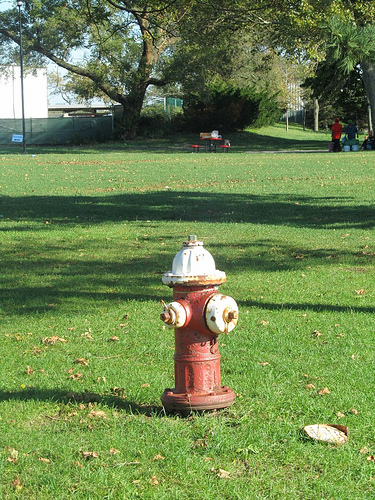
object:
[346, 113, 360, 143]
person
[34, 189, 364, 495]
leaves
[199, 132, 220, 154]
picnic table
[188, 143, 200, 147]
seat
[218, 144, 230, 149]
seat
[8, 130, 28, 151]
sign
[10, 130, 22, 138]
letters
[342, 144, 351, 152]
bucket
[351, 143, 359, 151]
bucket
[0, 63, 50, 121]
building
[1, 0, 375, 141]
tree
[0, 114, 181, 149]
fence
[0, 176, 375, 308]
shadows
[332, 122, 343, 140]
shirt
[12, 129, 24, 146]
sign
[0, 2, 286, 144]
tree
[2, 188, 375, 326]
shadow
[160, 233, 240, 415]
hydrant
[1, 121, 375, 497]
ground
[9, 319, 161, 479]
leaves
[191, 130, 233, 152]
bench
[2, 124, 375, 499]
grass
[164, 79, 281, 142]
bush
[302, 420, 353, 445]
paper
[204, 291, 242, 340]
plug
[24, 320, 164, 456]
leaves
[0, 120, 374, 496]
field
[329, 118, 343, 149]
person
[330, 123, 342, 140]
jacket